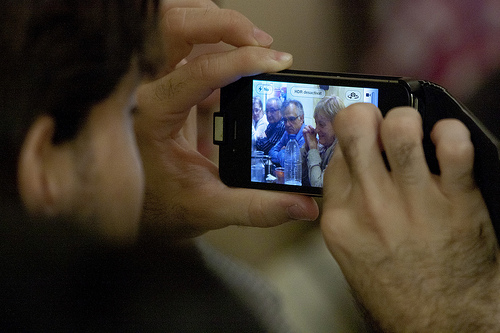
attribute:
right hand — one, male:
[317, 103, 495, 331]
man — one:
[1, 1, 173, 242]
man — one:
[269, 101, 309, 174]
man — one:
[258, 98, 283, 150]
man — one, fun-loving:
[0, 0, 499, 331]